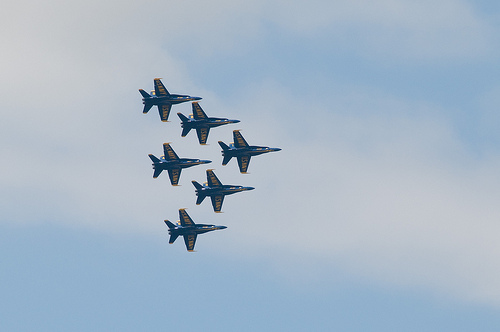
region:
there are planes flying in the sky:
[100, 59, 328, 294]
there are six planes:
[113, 31, 300, 299]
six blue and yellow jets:
[138, 57, 305, 282]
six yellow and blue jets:
[113, 50, 371, 317]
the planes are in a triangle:
[120, 33, 317, 325]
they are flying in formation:
[118, 29, 309, 280]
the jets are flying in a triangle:
[114, 30, 320, 320]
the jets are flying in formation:
[95, 15, 307, 287]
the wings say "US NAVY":
[168, 189, 217, 280]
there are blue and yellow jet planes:
[112, 23, 380, 328]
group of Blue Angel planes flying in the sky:
[114, 47, 314, 254]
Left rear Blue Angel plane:
[138, 69, 203, 124]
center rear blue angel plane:
[145, 140, 208, 185]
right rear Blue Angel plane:
[160, 205, 230, 250]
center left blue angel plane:
[178, 95, 236, 145]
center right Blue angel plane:
[191, 168, 270, 214]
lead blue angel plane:
[211, 125, 289, 179]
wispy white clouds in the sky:
[306, 120, 499, 275]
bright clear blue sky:
[34, 240, 249, 330]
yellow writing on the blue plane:
[233, 127, 250, 177]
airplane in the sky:
[136, 79, 198, 121]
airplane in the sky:
[169, 101, 244, 146]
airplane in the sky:
[214, 129, 284, 176]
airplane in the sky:
[191, 170, 254, 211]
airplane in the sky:
[161, 207, 229, 252]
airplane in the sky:
[141, 142, 214, 189]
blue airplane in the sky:
[135, 78, 202, 121]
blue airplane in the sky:
[173, 100, 243, 145]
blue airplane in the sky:
[216, 127, 280, 177]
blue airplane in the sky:
[193, 169, 262, 213]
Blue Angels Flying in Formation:
[130, 72, 291, 264]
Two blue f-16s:
[129, 69, 240, 143]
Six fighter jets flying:
[131, 65, 282, 253]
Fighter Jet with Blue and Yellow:
[220, 125, 296, 177]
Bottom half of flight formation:
[143, 135, 306, 262]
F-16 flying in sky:
[141, 142, 216, 187]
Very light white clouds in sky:
[307, 11, 492, 125]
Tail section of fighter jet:
[137, 75, 152, 117]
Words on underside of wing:
[236, 149, 253, 182]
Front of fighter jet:
[253, 135, 285, 167]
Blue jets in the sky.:
[137, 77, 282, 253]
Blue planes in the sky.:
[136, 75, 283, 252]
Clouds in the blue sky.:
[3, 0, 499, 329]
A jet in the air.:
[163, 205, 227, 252]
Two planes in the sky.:
[162, 167, 254, 250]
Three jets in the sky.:
[146, 140, 253, 250]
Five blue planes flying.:
[147, 100, 280, 251]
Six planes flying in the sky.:
[138, 76, 283, 252]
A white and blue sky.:
[3, 0, 496, 330]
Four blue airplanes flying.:
[147, 129, 282, 253]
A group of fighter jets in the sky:
[136, 73, 282, 254]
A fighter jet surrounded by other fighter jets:
[147, 142, 209, 185]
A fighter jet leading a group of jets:
[218, 128, 281, 172]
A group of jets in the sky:
[138, 74, 282, 253]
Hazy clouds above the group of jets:
[265, 84, 497, 309]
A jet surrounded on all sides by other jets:
[192, 168, 253, 213]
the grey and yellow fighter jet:
[192, 169, 256, 211]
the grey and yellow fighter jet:
[148, 140, 207, 185]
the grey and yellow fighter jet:
[217, 130, 278, 172]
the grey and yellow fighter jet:
[177, 99, 239, 142]